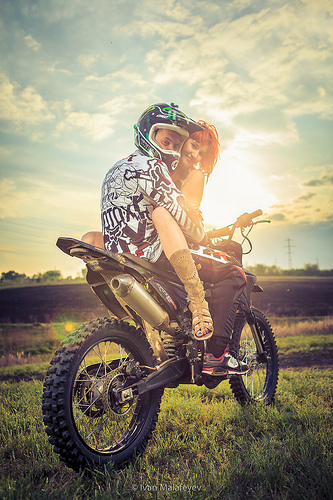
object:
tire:
[39, 317, 167, 475]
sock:
[206, 336, 226, 358]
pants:
[154, 243, 248, 343]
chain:
[82, 363, 121, 376]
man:
[98, 102, 250, 376]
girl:
[80, 119, 220, 342]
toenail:
[196, 331, 203, 337]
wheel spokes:
[71, 337, 146, 451]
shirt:
[100, 150, 204, 267]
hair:
[191, 119, 220, 185]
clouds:
[0, 0, 333, 103]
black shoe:
[201, 349, 250, 379]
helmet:
[132, 101, 205, 175]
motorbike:
[39, 208, 282, 480]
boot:
[168, 248, 216, 342]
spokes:
[239, 318, 272, 397]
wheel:
[226, 304, 280, 412]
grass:
[0, 309, 330, 500]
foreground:
[0, 102, 331, 497]